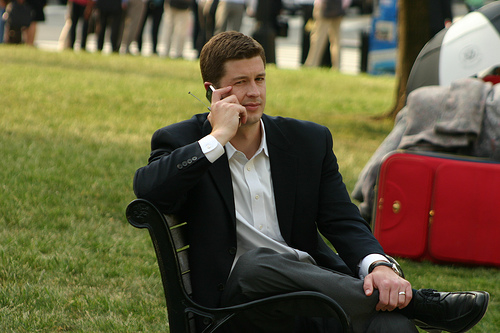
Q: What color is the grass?
A: Green.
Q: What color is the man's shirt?
A: White.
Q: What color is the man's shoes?
A: Black.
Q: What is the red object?
A: A piece of luggage.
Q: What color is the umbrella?
A: White and grey.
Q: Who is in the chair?
A: A man.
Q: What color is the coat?
A: Black.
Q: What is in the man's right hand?
A: Cell phone.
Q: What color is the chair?
A: Black.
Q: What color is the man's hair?
A: Brown.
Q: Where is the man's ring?
A: On his left hand.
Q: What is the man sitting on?
A: A bench.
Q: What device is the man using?
A: Cell phone.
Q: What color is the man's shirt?
A: White.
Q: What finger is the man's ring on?
A: His ring finger.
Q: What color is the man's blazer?
A: Black.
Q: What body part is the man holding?
A: His leg.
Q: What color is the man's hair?
A: Brown.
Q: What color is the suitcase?
A: Red and black.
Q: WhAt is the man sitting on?
A: A bench.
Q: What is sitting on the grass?
A: Red suitcase.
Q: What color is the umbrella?
A: Gray and white.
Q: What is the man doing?
A: Making a cell phone call.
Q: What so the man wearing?
A: Black jacket.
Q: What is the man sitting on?
A: Black park bench.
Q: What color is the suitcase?
A: Red.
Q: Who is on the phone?
A: The man.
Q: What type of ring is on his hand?
A: Wedding ring.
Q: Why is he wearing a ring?
A: Marriage.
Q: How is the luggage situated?
A: Ground.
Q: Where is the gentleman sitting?
A: At the park.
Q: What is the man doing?
A: Phone Call.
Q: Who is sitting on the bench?
A: A man.